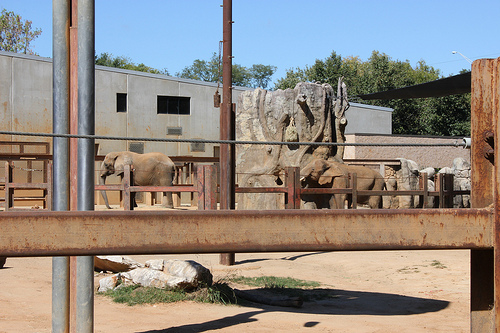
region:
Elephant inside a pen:
[83, 127, 189, 214]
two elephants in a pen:
[88, 128, 423, 207]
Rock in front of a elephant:
[242, 77, 359, 187]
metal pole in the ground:
[210, 15, 240, 206]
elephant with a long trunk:
[100, 168, 115, 209]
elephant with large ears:
[313, 164, 349, 181]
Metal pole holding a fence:
[28, 199, 483, 271]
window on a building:
[146, 88, 203, 121]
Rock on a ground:
[115, 250, 234, 319]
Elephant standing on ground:
[83, 120, 198, 221]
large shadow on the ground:
[146, 275, 445, 327]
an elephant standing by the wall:
[92, 151, 185, 206]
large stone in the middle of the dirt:
[227, 78, 345, 219]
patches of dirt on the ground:
[122, 265, 331, 299]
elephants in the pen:
[102, 149, 401, 211]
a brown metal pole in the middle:
[212, 2, 248, 272]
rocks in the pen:
[101, 256, 210, 291]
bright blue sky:
[8, 5, 498, 92]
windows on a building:
[111, 85, 195, 122]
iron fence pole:
[10, 164, 498, 260]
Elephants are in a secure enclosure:
[33, 47, 488, 297]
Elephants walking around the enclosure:
[60, 30, 495, 286]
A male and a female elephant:
[87, 62, 465, 267]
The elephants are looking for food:
[85, 50, 480, 300]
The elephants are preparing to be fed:
[82, 65, 473, 282]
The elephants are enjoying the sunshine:
[80, 65, 447, 275]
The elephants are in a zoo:
[85, 55, 485, 270]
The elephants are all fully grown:
[95, 90, 455, 286]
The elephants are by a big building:
[30, 60, 475, 305]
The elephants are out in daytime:
[75, 85, 466, 298]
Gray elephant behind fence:
[95, 148, 180, 205]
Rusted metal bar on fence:
[1, 204, 498, 246]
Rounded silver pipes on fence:
[53, 32, 96, 332]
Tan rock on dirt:
[101, 255, 217, 291]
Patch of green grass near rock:
[114, 281, 236, 301]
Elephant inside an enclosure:
[304, 158, 389, 208]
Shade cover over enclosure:
[358, 72, 498, 99]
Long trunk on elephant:
[97, 170, 115, 211]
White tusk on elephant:
[299, 173, 306, 181]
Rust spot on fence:
[479, 230, 485, 240]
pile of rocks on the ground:
[100, 255, 217, 303]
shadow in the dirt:
[179, 281, 437, 331]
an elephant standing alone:
[92, 143, 189, 206]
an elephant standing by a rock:
[285, 157, 399, 211]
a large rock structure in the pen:
[239, 83, 341, 208]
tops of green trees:
[2, 12, 492, 142]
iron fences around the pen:
[4, 139, 496, 253]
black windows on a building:
[110, 90, 201, 121]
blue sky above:
[3, 0, 498, 72]